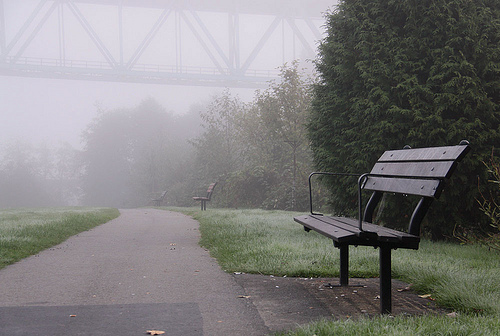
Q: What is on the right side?
A: Green grass.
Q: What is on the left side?
A: Green grass.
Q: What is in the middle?
A: The road.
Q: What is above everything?
A: Bridge.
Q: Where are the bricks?
A: Under the bench.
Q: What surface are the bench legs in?
A: Grass.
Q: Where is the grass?
A: Between the benches.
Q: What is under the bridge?
A: Trees.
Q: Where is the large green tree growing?
A: In the grass to the right.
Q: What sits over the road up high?
A: A bridge.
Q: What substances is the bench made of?
A: Wood and metal.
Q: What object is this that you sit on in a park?
A: Bench.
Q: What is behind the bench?
A: Trees.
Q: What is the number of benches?
A: 3.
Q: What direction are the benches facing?
A: To the left.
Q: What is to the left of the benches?
A: Sidewalk.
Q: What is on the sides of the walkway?
A: Grass.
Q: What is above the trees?
A: Bridge.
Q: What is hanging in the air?
A: Fog.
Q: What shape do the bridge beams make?
A: Triangles.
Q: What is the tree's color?
A: Green.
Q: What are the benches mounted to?
A: Cement.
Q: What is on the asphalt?
A: Leaves.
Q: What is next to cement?
A: Bench.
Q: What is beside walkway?
A: Bench.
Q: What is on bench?
A: Metal arms.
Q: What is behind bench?
A: Large shrubbery.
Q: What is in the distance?
A: Fog.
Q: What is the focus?
A: Park benches in the foggy rain.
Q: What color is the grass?
A: Green.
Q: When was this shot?
A: Daytime.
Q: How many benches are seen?
A: 3.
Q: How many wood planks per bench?
A: 7.